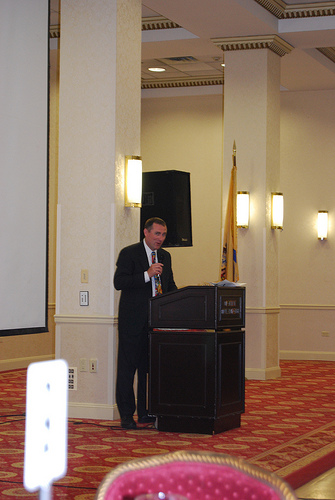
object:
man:
[111, 217, 179, 431]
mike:
[157, 253, 166, 281]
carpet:
[0, 376, 333, 484]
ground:
[296, 465, 335, 497]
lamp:
[124, 155, 143, 208]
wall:
[56, 0, 120, 242]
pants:
[116, 331, 149, 420]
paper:
[209, 279, 247, 289]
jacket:
[113, 240, 178, 335]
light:
[316, 210, 327, 242]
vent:
[160, 55, 198, 63]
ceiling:
[47, 0, 335, 89]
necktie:
[151, 251, 162, 296]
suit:
[113, 238, 178, 430]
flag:
[218, 165, 239, 284]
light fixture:
[271, 190, 285, 230]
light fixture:
[235, 189, 251, 229]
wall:
[279, 89, 335, 354]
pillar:
[219, 46, 281, 383]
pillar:
[53, 1, 142, 429]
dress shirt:
[142, 238, 164, 297]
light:
[146, 65, 168, 73]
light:
[220, 61, 225, 68]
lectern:
[147, 284, 246, 435]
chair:
[93, 447, 298, 500]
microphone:
[156, 251, 165, 280]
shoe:
[120, 416, 136, 430]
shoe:
[138, 415, 151, 423]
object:
[140, 169, 193, 248]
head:
[143, 216, 168, 250]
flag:
[218, 137, 239, 285]